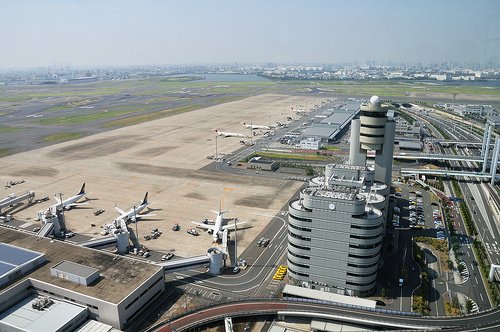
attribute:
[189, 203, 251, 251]
plane — part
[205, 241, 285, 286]
runway — part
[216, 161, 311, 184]
runway — part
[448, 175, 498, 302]
runway — part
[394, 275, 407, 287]
truck — white 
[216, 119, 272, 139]
planes — disant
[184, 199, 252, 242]
plane — part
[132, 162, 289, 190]
runway — part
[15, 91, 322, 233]
runway — part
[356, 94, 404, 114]
object — white 